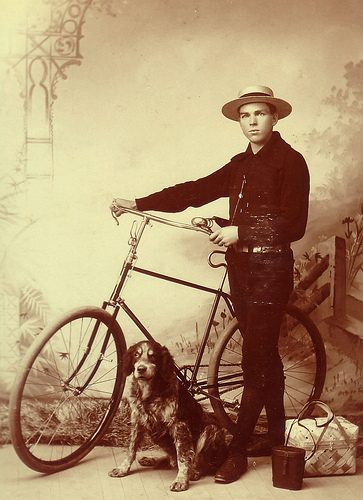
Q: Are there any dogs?
A: Yes, there is a dog.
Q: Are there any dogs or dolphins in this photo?
A: Yes, there is a dog.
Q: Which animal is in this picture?
A: The animal is a dog.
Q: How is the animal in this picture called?
A: The animal is a dog.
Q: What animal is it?
A: The animal is a dog.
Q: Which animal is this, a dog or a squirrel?
A: This is a dog.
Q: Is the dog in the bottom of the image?
A: Yes, the dog is in the bottom of the image.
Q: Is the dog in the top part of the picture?
A: No, the dog is in the bottom of the image.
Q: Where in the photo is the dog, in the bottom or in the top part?
A: The dog is in the bottom of the image.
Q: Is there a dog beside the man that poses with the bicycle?
A: Yes, there is a dog beside the man.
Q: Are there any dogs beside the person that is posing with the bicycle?
A: Yes, there is a dog beside the man.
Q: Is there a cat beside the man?
A: No, there is a dog beside the man.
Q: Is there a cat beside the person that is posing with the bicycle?
A: No, there is a dog beside the man.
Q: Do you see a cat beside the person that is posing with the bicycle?
A: No, there is a dog beside the man.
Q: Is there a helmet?
A: No, there are no helmets.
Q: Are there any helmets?
A: No, there are no helmets.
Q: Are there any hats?
A: Yes, there is a hat.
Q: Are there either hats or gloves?
A: Yes, there is a hat.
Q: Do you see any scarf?
A: No, there are no scarves.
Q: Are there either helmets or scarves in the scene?
A: No, there are no scarves or helmets.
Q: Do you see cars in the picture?
A: No, there are no cars.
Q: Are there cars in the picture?
A: No, there are no cars.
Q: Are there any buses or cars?
A: No, there are no cars or buses.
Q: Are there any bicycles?
A: Yes, there is a bicycle.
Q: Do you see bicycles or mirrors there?
A: Yes, there is a bicycle.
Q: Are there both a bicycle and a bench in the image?
A: No, there is a bicycle but no benches.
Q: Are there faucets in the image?
A: No, there are no faucets.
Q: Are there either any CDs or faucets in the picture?
A: No, there are no faucets or cds.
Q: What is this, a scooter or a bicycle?
A: This is a bicycle.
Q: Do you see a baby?
A: No, there are no babies.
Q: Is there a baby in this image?
A: No, there are no babies.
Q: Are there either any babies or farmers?
A: No, there are no babies or farmers.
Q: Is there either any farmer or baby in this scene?
A: No, there are no babies or farmers.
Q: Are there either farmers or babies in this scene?
A: No, there are no babies or farmers.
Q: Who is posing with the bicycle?
A: The man is posing with the bicycle.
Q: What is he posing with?
A: The man is posing with the bicycle.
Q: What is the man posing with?
A: The man is posing with the bicycle.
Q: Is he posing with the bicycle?
A: Yes, the man is posing with the bicycle.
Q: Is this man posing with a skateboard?
A: No, the man is posing with the bicycle.